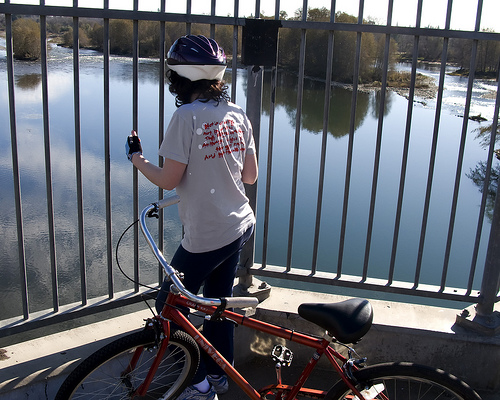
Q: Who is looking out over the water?
A: The girl with the bike.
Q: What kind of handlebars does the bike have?
A: Silver.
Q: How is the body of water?
A: Calm.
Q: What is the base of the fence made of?
A: Concrete.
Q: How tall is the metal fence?
A: Taller than the girl.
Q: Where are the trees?
A: Across the water.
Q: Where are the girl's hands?
A: Holding the metal bars.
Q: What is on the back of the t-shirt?
A: Red writing.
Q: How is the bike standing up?
A: Kickstand.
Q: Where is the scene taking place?
A: Beside a lake.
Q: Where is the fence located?
A: In front of the boy.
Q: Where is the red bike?
A: Behind the boy.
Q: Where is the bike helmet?
A: On the boys head.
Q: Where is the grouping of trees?
A: On small island in middle of lake.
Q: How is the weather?
A: Warm and sunny.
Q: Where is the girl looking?
A: At the lake.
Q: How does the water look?
A: Clear and calm.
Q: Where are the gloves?
A: On girls hands.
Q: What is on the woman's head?
A: Bicycle helmet.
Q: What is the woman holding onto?
A: Fence railings.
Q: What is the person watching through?
A: Iron bars.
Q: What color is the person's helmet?
A: White and black.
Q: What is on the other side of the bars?
A: A lake.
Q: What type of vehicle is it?
A: A bicycle.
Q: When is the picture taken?
A: During daytime.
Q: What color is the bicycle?
A: Red and black.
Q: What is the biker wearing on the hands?
A: Gloves.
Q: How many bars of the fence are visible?
A: 19.